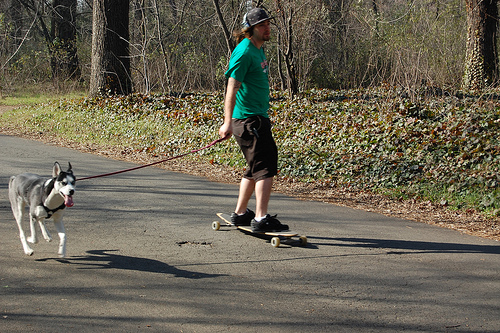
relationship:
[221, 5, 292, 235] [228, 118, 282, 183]
man wearing shorts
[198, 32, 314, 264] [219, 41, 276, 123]
man wearing shirt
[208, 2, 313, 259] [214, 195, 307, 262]
man riding skateboard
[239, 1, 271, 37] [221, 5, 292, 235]
cap on man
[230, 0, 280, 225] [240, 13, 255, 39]
man wearing headphones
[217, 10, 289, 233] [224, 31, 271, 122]
man wearing shirt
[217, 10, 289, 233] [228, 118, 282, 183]
man wearing shorts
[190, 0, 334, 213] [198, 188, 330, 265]
man wearing black shoes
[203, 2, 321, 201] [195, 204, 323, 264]
man riding black skateboard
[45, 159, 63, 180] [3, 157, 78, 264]
ear on dog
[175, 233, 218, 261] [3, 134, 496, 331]
pothole in asphalt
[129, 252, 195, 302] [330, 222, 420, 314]
shadow on ground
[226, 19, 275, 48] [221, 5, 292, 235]
hair on man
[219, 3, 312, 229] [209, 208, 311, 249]
man riding skateboard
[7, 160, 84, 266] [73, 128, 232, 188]
dog wearing leash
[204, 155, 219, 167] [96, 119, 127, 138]
leaves are in grass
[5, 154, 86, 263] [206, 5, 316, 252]
dog running with skateboarder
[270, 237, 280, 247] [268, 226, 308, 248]
wheel on skateboard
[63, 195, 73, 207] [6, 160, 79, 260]
tongue in dog